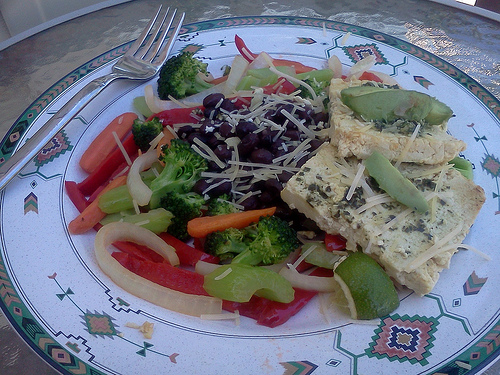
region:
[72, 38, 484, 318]
a salad on a plate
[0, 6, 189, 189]
metal fork on a plate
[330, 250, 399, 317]
a cut piece of lime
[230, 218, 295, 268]
a piece of brocolli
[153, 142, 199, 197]
a piece of brocolli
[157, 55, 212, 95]
a piece of brocolli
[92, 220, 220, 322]
a slice of onion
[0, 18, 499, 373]
a white patterened plate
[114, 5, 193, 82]
head of a fork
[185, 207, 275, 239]
a piece of a carrot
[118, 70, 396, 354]
salad on the plate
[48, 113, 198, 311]
salad on the plate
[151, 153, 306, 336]
salad on the plate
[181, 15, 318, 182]
salad on the plate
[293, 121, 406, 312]
tofu with cheese on top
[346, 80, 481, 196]
tofu with cheese on top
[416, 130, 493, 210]
tofu with cheese on top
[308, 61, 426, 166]
tofu with cheese on top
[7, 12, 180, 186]
silver fork sitting on plate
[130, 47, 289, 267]
broccoli on plate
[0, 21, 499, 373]
white plate with multi colored pattern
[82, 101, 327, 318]
slices of red pepper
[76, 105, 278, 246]
slices of ornage carrot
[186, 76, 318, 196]
shredded food topping dish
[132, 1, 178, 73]
tines of silver fork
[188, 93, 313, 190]
black beans in center of other food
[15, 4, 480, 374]
silver table plate is on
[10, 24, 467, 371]
plate filled with colorful food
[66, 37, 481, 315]
colorful mixed vegetable meal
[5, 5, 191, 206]
stainless steel fork resting on a plate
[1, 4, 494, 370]
Native American decorated white plate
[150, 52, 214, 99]
piece of broccoli crown in a mixed vegetable meal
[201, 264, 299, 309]
piece of celery in a mixed vegetable meal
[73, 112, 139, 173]
piece of carrot in a mixed vegetable meal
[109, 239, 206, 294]
red pepper in a mixed vegetable meal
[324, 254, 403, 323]
wedge of lime garnish in a mixed vegetable meal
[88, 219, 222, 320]
piece of onion in a mixed vegetable meal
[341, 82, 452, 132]
piece of green pepper in a mixed vegetable meal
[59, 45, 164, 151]
Fork on a plate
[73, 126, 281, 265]
Vegetables on a plate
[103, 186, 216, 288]
peppers on a plate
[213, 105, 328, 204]
cheese on a salad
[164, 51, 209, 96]
broccoli in a salad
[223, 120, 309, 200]
beans in a salad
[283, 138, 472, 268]
tofu in a salad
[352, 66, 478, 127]
avocado in a salad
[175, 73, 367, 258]
beans in a plate of food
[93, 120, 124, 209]
carrots in a salad